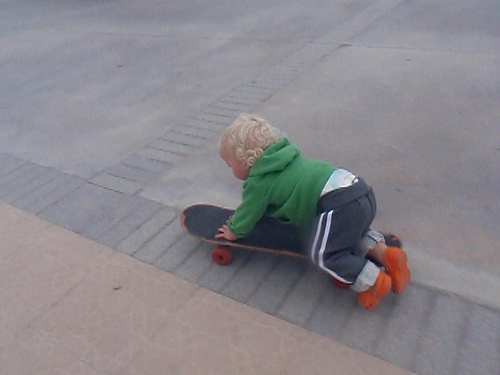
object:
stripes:
[317, 209, 352, 284]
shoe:
[385, 246, 410, 296]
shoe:
[355, 270, 392, 311]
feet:
[382, 245, 410, 293]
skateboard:
[180, 203, 402, 288]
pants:
[308, 177, 386, 295]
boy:
[213, 112, 411, 309]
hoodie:
[225, 136, 337, 240]